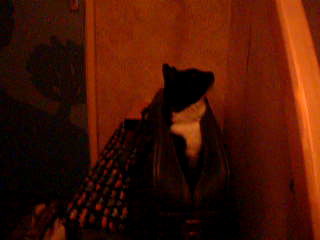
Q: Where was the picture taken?
A: In a dark room.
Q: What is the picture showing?
A: A bag with clothes hanging out.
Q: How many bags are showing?
A: One.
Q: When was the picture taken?
A: At night.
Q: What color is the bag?
A: Black.